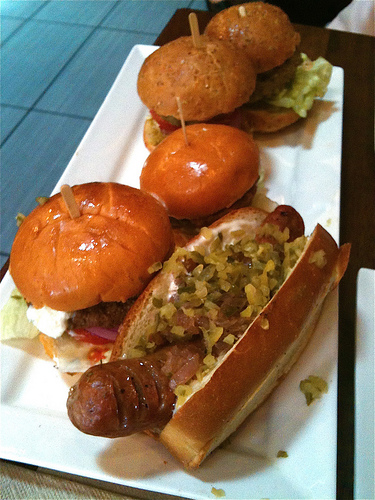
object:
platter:
[0, 48, 345, 499]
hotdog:
[70, 206, 352, 471]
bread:
[111, 205, 342, 470]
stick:
[60, 183, 81, 220]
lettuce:
[277, 55, 331, 125]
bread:
[7, 185, 185, 381]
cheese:
[52, 338, 113, 371]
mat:
[0, 462, 140, 497]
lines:
[5, 469, 22, 499]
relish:
[129, 222, 309, 362]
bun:
[139, 125, 261, 219]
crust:
[139, 32, 257, 152]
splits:
[110, 364, 169, 428]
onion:
[76, 320, 121, 348]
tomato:
[148, 105, 178, 134]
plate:
[352, 268, 374, 498]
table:
[0, 10, 373, 500]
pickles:
[209, 261, 248, 286]